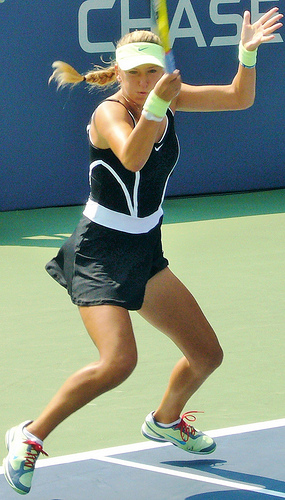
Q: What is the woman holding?
A: A tennis racket.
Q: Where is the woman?
A: A tennis court.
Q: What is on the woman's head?
A: A hat.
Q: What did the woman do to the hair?
A: Put it in a braid.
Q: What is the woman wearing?
A: A shirt and skirt.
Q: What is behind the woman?
A: A wall.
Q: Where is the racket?
A: In the woman's hand.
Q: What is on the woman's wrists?
A: Wristbands.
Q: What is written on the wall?
A: Chase.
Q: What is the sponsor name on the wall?
A: CHASE.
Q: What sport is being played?
A: Tennis.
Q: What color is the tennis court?
A: The tennis court is green and blue.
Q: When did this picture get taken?
A: It was taken in the day time.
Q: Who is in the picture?
A: A woman is in the picture.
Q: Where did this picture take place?
A: It took place on a tennis court.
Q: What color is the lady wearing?
A: She is wearing all black.